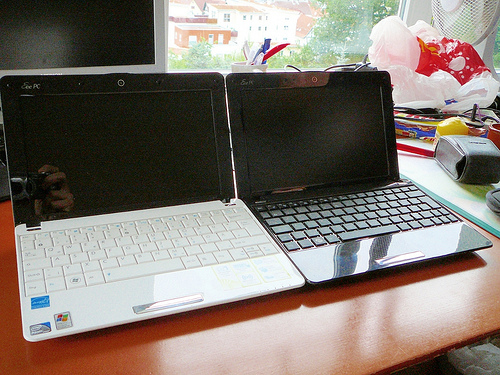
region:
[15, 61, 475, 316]
two laptops sitting next to each other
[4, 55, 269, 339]
a white laptop computer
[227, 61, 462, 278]
a black laptop computer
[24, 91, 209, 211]
the screen of a laptop computer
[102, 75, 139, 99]
the webcam of a laptop computer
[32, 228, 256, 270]
the keyboard of a laptop computer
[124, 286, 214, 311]
the touchpad of a laptop computer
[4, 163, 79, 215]
a reflection of a photographer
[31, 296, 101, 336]
the logo stickers of a laptop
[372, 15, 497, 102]
a white plastic grocery bag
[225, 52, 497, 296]
This is a laptop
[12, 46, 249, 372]
This is a laptop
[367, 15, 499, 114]
a shopping bag on a pile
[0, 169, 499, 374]
a wooden desk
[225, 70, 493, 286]
a black laptop on the desk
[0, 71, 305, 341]
a white laptop on the desk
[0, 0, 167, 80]
a computer monitor on the desk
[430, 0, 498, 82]
a white fan on the desk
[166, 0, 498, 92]
a large window in the background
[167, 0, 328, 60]
a large group of buildings outside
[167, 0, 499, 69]
a large group of plants outside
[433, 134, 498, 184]
a carrying case on the desk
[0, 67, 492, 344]
two laptops sitting on desk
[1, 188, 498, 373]
desk is made of wood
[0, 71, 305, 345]
left laptop is white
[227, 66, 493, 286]
laptop on right is blue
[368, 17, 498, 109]
plastic bag by window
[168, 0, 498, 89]
glass window behind computers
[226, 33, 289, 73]
cup full of pens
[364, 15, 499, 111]
white and red plastic bag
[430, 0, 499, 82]
white fan on desk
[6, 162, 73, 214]
the persons hand is being reflected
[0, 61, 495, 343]
Laptops on a table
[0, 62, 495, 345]
Laptops are on a table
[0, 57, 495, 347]
Laptops on a brown table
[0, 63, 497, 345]
Laptops are on a brown table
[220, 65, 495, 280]
Black laptop on a table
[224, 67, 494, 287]
Black laptop is on a table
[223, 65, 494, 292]
Black laptop on a brown table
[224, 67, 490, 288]
Black laptop is on a brown table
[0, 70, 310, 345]
Black and white laptop on a table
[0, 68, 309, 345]
Black and white laptop on a brown table